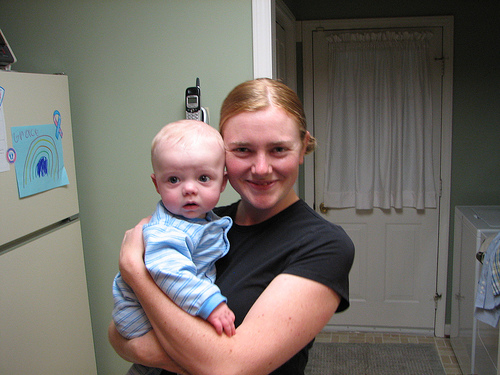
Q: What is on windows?
A: White curtains.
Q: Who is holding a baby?
A: A woman.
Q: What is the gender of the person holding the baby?
A: Female.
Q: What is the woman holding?
A: A baby.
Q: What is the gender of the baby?
A: Male.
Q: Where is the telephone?
A: Behind the baby.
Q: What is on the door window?
A: Curtain.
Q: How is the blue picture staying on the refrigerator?
A: Magnet.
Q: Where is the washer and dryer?
A: Beside the door.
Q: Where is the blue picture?
A: On the refrigerator.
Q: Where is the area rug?
A: In front of the door.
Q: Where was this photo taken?
A: In the kitchen.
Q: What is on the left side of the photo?
A: A fridge.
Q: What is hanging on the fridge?
A: A picture.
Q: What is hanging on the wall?
A: A phone.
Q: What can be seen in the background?
A: A door.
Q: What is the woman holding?
A: A baby.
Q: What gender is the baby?
A: Male.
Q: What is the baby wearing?
A: A sleeper.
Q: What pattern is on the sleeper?
A: Stripes.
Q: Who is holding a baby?
A: The woman.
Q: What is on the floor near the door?
A: Carpet.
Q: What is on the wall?
A: Phone.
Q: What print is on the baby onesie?
A: Striped.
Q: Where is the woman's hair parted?
A: The side.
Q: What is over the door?
A: Curtain.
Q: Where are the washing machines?
A: Right wall.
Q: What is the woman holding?
A: A baby.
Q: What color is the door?
A: White.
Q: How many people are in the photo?
A: Two.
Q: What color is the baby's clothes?
A: Blue and white.